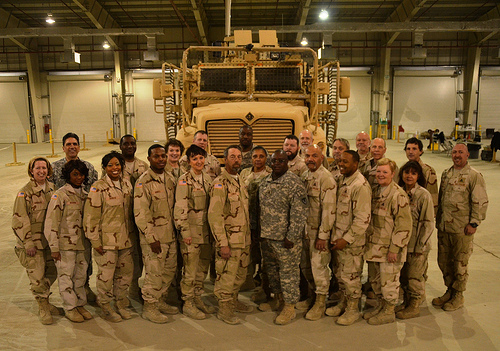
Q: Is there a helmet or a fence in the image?
A: No, there are no helmets or fences.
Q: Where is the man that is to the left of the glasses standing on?
A: The man is standing on the ground.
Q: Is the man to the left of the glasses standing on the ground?
A: Yes, the man is standing on the ground.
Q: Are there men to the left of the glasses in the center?
A: Yes, there is a man to the left of the glasses.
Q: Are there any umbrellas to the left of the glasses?
A: No, there is a man to the left of the glasses.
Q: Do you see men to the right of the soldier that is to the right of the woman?
A: Yes, there is a man to the right of the soldier.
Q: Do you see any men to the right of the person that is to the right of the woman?
A: Yes, there is a man to the right of the soldier.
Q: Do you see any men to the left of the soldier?
A: No, the man is to the right of the soldier.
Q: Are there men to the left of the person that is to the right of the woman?
A: No, the man is to the right of the soldier.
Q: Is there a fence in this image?
A: No, there are no fences.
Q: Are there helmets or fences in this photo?
A: No, there are no fences or helmets.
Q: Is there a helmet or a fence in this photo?
A: No, there are no fences or helmets.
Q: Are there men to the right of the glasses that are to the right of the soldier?
A: Yes, there is a man to the right of the glasses.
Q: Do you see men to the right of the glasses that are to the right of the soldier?
A: Yes, there is a man to the right of the glasses.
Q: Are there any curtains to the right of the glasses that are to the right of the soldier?
A: No, there is a man to the right of the glasses.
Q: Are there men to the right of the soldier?
A: Yes, there is a man to the right of the soldier.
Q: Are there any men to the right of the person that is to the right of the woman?
A: Yes, there is a man to the right of the soldier.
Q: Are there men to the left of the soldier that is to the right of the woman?
A: No, the man is to the right of the soldier.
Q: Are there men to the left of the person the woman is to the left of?
A: No, the man is to the right of the soldier.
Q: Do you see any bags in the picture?
A: No, there are no bags.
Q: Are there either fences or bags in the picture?
A: No, there are no bags or fences.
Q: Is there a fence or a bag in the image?
A: No, there are no bags or fences.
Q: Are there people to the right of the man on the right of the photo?
A: Yes, there is a person to the right of the man.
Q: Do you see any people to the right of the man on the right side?
A: Yes, there is a person to the right of the man.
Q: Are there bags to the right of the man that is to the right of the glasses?
A: No, there is a person to the right of the man.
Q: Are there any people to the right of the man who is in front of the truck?
A: Yes, there is a person to the right of the man.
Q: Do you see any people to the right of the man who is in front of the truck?
A: Yes, there is a person to the right of the man.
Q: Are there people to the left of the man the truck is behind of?
A: No, the person is to the right of the man.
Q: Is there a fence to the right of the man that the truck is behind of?
A: No, there is a person to the right of the man.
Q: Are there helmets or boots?
A: Yes, there are boots.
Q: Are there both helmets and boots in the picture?
A: No, there are boots but no helmets.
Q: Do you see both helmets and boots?
A: No, there are boots but no helmets.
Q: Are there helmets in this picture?
A: No, there are no helmets.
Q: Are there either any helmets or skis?
A: No, there are no helmets or skis.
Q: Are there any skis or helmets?
A: No, there are no helmets or skis.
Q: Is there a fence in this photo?
A: No, there are no fences.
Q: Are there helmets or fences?
A: No, there are no fences or helmets.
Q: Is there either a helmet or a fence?
A: No, there are no fences or helmets.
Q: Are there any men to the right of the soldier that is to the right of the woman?
A: Yes, there is a man to the right of the soldier.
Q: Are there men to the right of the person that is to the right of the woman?
A: Yes, there is a man to the right of the soldier.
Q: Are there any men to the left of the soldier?
A: No, the man is to the right of the soldier.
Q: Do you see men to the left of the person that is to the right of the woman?
A: No, the man is to the right of the soldier.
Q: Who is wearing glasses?
A: The man is wearing glasses.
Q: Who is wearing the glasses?
A: The man is wearing glasses.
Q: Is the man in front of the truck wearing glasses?
A: Yes, the man is wearing glasses.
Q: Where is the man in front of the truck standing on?
A: The man is standing on the ground.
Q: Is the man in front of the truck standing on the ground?
A: Yes, the man is standing on the ground.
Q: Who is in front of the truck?
A: The man is in front of the truck.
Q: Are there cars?
A: No, there are no cars.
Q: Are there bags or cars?
A: No, there are no cars or bags.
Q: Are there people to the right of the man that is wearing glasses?
A: Yes, there is a person to the right of the man.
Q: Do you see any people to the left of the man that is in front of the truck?
A: No, the person is to the right of the man.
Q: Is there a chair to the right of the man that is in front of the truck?
A: No, there is a person to the right of the man.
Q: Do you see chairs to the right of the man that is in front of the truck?
A: No, there is a person to the right of the man.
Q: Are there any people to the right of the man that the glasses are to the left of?
A: Yes, there is a person to the right of the man.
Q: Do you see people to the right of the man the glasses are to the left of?
A: Yes, there is a person to the right of the man.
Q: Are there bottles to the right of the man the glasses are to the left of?
A: No, there is a person to the right of the man.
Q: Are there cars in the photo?
A: No, there are no cars.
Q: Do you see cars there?
A: No, there are no cars.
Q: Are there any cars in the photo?
A: No, there are no cars.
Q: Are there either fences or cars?
A: No, there are no cars or fences.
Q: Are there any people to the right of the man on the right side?
A: Yes, there is a person to the right of the man.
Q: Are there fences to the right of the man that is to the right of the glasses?
A: No, there is a person to the right of the man.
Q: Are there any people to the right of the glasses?
A: Yes, there is a person to the right of the glasses.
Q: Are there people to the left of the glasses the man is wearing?
A: No, the person is to the right of the glasses.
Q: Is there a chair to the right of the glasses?
A: No, there is a person to the right of the glasses.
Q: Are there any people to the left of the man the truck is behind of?
A: No, the person is to the right of the man.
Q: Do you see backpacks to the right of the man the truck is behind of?
A: No, there is a person to the right of the man.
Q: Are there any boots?
A: Yes, there are boots.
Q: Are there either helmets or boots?
A: Yes, there are boots.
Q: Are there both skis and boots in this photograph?
A: No, there are boots but no skis.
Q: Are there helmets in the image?
A: No, there are no helmets.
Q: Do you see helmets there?
A: No, there are no helmets.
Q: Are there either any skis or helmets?
A: No, there are no helmets or skis.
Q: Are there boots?
A: Yes, there are boots.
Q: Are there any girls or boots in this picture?
A: Yes, there are boots.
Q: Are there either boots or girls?
A: Yes, there are boots.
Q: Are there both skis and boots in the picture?
A: No, there are boots but no skis.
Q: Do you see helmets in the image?
A: No, there are no helmets.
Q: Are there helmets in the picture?
A: No, there are no helmets.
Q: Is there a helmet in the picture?
A: No, there are no helmets.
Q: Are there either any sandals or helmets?
A: No, there are no helmets or sandals.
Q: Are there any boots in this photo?
A: Yes, there are boots.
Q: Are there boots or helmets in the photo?
A: Yes, there are boots.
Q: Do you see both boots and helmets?
A: No, there are boots but no helmets.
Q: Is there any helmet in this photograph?
A: No, there are no helmets.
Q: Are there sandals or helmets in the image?
A: No, there are no helmets or sandals.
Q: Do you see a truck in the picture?
A: Yes, there is a truck.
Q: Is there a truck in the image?
A: Yes, there is a truck.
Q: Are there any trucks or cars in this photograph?
A: Yes, there is a truck.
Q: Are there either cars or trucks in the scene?
A: Yes, there is a truck.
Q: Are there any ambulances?
A: No, there are no ambulances.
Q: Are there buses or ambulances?
A: No, there are no ambulances or buses.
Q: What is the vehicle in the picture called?
A: The vehicle is a truck.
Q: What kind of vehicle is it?
A: The vehicle is a truck.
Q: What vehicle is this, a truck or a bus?
A: That is a truck.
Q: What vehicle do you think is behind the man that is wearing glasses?
A: The vehicle is a truck.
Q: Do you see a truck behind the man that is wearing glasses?
A: Yes, there is a truck behind the man.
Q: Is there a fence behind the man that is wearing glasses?
A: No, there is a truck behind the man.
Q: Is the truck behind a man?
A: Yes, the truck is behind a man.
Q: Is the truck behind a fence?
A: No, the truck is behind a man.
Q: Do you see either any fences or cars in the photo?
A: No, there are no fences or cars.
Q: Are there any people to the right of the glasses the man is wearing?
A: Yes, there is a person to the right of the glasses.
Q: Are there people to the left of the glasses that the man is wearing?
A: No, the person is to the right of the glasses.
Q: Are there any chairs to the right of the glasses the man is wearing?
A: No, there is a person to the right of the glasses.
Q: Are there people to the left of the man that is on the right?
A: Yes, there is a person to the left of the man.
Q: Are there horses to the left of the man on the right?
A: No, there is a person to the left of the man.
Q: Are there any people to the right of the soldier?
A: Yes, there is a person to the right of the soldier.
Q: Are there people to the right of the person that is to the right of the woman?
A: Yes, there is a person to the right of the soldier.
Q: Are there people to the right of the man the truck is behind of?
A: Yes, there is a person to the right of the man.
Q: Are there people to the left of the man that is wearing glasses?
A: No, the person is to the right of the man.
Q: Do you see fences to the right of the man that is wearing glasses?
A: No, there is a person to the right of the man.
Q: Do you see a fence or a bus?
A: No, there are no fences or buses.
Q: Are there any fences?
A: No, there are no fences.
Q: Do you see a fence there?
A: No, there are no fences.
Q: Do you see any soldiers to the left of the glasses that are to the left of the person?
A: Yes, there is a soldier to the left of the glasses.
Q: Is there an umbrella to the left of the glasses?
A: No, there is a soldier to the left of the glasses.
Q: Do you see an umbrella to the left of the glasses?
A: No, there is a soldier to the left of the glasses.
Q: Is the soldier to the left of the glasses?
A: Yes, the soldier is to the left of the glasses.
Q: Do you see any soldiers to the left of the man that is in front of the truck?
A: Yes, there is a soldier to the left of the man.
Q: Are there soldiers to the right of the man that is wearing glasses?
A: No, the soldier is to the left of the man.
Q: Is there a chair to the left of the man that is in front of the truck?
A: No, there is a soldier to the left of the man.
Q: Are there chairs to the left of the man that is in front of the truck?
A: No, there is a soldier to the left of the man.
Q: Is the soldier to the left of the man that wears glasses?
A: Yes, the soldier is to the left of the man.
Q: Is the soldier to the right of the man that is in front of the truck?
A: No, the soldier is to the left of the man.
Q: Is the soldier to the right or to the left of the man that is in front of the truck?
A: The soldier is to the left of the man.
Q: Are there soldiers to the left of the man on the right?
A: Yes, there is a soldier to the left of the man.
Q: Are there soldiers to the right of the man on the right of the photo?
A: No, the soldier is to the left of the man.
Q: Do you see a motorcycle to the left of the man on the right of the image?
A: No, there is a soldier to the left of the man.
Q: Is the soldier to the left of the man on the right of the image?
A: Yes, the soldier is to the left of the man.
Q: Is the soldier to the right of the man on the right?
A: No, the soldier is to the left of the man.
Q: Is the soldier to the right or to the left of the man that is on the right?
A: The soldier is to the left of the man.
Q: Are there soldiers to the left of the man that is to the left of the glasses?
A: Yes, there is a soldier to the left of the man.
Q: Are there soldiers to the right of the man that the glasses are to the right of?
A: No, the soldier is to the left of the man.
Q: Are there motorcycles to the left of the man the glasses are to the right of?
A: No, there is a soldier to the left of the man.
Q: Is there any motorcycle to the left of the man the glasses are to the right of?
A: No, there is a soldier to the left of the man.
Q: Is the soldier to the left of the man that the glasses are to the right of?
A: Yes, the soldier is to the left of the man.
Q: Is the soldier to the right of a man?
A: No, the soldier is to the left of a man.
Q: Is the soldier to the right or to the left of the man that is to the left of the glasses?
A: The soldier is to the left of the man.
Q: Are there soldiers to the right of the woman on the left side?
A: Yes, there is a soldier to the right of the woman.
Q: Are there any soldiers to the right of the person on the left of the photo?
A: Yes, there is a soldier to the right of the woman.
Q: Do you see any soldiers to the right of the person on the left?
A: Yes, there is a soldier to the right of the woman.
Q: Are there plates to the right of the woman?
A: No, there is a soldier to the right of the woman.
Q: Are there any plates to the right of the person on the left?
A: No, there is a soldier to the right of the woman.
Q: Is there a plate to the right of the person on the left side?
A: No, there is a soldier to the right of the woman.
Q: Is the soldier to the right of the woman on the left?
A: Yes, the soldier is to the right of the woman.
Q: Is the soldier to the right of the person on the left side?
A: Yes, the soldier is to the right of the woman.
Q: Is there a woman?
A: Yes, there is a woman.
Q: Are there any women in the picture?
A: Yes, there is a woman.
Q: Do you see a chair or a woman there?
A: Yes, there is a woman.